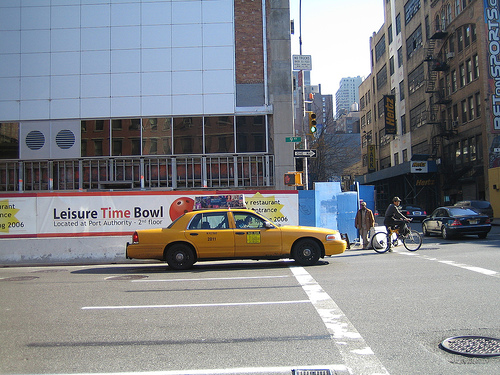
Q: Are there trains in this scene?
A: No, there are no trains.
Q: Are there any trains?
A: No, there are no trains.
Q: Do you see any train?
A: No, there are no trains.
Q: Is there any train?
A: No, there are no trains.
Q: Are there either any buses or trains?
A: No, there are no trains or buses.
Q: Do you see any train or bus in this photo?
A: No, there are no trains or buses.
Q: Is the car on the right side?
A: Yes, the car is on the right of the image.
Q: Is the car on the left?
A: No, the car is on the right of the image.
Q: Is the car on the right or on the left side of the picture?
A: The car is on the right of the image.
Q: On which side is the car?
A: The car is on the right of the image.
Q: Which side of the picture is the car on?
A: The car is on the right of the image.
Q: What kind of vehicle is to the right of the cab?
A: The vehicle is a car.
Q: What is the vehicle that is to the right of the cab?
A: The vehicle is a car.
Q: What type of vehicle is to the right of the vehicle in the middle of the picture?
A: The vehicle is a car.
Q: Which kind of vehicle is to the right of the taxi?
A: The vehicle is a car.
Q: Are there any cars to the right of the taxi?
A: Yes, there is a car to the right of the taxi.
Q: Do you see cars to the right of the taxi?
A: Yes, there is a car to the right of the taxi.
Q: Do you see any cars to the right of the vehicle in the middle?
A: Yes, there is a car to the right of the taxi.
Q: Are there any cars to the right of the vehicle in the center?
A: Yes, there is a car to the right of the taxi.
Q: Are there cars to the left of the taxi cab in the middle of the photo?
A: No, the car is to the right of the cab.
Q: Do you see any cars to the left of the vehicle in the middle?
A: No, the car is to the right of the cab.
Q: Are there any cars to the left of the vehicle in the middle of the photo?
A: No, the car is to the right of the cab.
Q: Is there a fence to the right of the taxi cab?
A: No, there is a car to the right of the taxi cab.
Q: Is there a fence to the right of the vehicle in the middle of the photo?
A: No, there is a car to the right of the taxi cab.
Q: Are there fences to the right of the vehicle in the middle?
A: No, there is a car to the right of the taxi cab.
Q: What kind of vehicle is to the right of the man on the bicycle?
A: The vehicle is a car.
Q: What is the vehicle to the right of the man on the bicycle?
A: The vehicle is a car.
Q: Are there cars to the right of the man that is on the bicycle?
A: Yes, there is a car to the right of the man.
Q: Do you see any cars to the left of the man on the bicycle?
A: No, the car is to the right of the man.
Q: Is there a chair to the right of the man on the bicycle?
A: No, there is a car to the right of the man.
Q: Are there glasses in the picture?
A: No, there are no glasses.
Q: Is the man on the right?
A: Yes, the man is on the right of the image.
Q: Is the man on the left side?
A: No, the man is on the right of the image.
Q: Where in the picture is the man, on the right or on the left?
A: The man is on the right of the image.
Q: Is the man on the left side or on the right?
A: The man is on the right of the image.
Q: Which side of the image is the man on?
A: The man is on the right of the image.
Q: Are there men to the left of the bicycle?
A: Yes, there is a man to the left of the bicycle.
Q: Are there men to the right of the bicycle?
A: No, the man is to the left of the bicycle.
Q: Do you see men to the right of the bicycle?
A: No, the man is to the left of the bicycle.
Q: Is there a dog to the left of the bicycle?
A: No, there is a man to the left of the bicycle.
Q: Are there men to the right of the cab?
A: Yes, there is a man to the right of the cab.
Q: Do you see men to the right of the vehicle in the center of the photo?
A: Yes, there is a man to the right of the cab.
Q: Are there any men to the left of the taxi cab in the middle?
A: No, the man is to the right of the cab.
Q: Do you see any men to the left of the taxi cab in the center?
A: No, the man is to the right of the cab.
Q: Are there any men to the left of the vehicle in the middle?
A: No, the man is to the right of the cab.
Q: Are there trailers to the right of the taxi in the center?
A: No, there is a man to the right of the taxi cab.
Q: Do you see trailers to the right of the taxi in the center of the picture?
A: No, there is a man to the right of the taxi cab.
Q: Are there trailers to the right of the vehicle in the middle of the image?
A: No, there is a man to the right of the taxi cab.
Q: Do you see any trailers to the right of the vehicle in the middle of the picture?
A: No, there is a man to the right of the taxi cab.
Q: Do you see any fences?
A: No, there are no fences.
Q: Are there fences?
A: No, there are no fences.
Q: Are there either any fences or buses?
A: No, there are no fences or buses.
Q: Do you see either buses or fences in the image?
A: No, there are no fences or buses.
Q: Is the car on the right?
A: Yes, the car is on the right of the image.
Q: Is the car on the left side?
A: No, the car is on the right of the image.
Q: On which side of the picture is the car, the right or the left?
A: The car is on the right of the image.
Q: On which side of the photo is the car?
A: The car is on the right of the image.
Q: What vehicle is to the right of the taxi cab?
A: The vehicle is a car.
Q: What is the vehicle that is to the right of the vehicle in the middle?
A: The vehicle is a car.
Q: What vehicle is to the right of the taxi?
A: The vehicle is a car.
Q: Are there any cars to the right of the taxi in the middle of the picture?
A: Yes, there is a car to the right of the cab.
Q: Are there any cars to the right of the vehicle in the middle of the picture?
A: Yes, there is a car to the right of the cab.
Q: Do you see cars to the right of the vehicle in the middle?
A: Yes, there is a car to the right of the cab.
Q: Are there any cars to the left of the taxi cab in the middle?
A: No, the car is to the right of the taxi.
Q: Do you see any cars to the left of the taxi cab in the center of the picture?
A: No, the car is to the right of the taxi.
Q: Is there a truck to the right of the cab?
A: No, there is a car to the right of the cab.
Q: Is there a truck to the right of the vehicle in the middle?
A: No, there is a car to the right of the cab.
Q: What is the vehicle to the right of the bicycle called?
A: The vehicle is a car.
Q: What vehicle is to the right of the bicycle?
A: The vehicle is a car.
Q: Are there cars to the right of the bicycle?
A: Yes, there is a car to the right of the bicycle.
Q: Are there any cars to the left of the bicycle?
A: No, the car is to the right of the bicycle.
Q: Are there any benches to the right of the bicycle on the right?
A: No, there is a car to the right of the bicycle.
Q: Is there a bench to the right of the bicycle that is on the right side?
A: No, there is a car to the right of the bicycle.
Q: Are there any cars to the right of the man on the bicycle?
A: Yes, there is a car to the right of the man.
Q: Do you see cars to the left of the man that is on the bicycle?
A: No, the car is to the right of the man.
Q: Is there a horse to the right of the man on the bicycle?
A: No, there is a car to the right of the man.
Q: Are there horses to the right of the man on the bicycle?
A: No, there is a car to the right of the man.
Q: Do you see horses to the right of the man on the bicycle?
A: No, there is a car to the right of the man.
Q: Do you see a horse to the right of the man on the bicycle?
A: No, there is a car to the right of the man.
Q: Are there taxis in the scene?
A: Yes, there is a taxi.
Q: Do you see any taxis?
A: Yes, there is a taxi.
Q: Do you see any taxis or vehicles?
A: Yes, there is a taxi.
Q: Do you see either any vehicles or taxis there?
A: Yes, there is a taxi.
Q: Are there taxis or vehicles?
A: Yes, there is a taxi.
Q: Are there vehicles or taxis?
A: Yes, there is a taxi.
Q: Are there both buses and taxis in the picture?
A: No, there is a taxi but no buses.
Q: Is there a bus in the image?
A: No, there are no buses.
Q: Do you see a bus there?
A: No, there are no buses.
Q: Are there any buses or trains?
A: No, there are no buses or trains.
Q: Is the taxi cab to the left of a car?
A: Yes, the taxi cab is to the left of a car.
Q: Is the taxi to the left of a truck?
A: No, the taxi is to the left of a car.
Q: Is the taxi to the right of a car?
A: No, the taxi is to the left of a car.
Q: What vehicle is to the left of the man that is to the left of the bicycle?
A: The vehicle is a taxi.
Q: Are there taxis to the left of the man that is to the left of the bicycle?
A: Yes, there is a taxi to the left of the man.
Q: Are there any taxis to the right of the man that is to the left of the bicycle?
A: No, the taxi is to the left of the man.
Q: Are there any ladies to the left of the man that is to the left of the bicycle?
A: No, there is a taxi to the left of the man.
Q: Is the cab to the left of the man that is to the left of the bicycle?
A: Yes, the cab is to the left of the man.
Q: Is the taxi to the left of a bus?
A: No, the taxi is to the left of the man.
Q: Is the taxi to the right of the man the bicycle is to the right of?
A: No, the taxi is to the left of the man.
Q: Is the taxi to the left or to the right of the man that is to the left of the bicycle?
A: The taxi is to the left of the man.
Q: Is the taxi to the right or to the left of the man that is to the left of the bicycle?
A: The taxi is to the left of the man.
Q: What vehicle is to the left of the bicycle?
A: The vehicle is a taxi.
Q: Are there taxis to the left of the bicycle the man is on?
A: Yes, there is a taxi to the left of the bicycle.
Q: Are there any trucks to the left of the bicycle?
A: No, there is a taxi to the left of the bicycle.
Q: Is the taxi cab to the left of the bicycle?
A: Yes, the taxi cab is to the left of the bicycle.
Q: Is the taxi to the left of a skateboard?
A: No, the taxi is to the left of the bicycle.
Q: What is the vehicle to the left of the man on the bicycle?
A: The vehicle is a taxi.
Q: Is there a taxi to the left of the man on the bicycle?
A: Yes, there is a taxi to the left of the man.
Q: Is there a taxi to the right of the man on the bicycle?
A: No, the taxi is to the left of the man.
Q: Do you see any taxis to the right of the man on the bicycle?
A: No, the taxi is to the left of the man.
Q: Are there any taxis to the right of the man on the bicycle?
A: No, the taxi is to the left of the man.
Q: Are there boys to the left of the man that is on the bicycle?
A: No, there is a taxi to the left of the man.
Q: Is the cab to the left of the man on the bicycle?
A: Yes, the cab is to the left of the man.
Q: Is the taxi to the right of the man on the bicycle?
A: No, the taxi is to the left of the man.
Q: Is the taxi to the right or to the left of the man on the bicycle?
A: The taxi is to the left of the man.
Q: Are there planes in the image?
A: No, there are no planes.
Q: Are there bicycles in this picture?
A: Yes, there is a bicycle.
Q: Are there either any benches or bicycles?
A: Yes, there is a bicycle.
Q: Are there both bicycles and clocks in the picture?
A: No, there is a bicycle but no clocks.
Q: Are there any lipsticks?
A: No, there are no lipsticks.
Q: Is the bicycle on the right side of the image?
A: Yes, the bicycle is on the right of the image.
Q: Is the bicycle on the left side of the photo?
A: No, the bicycle is on the right of the image.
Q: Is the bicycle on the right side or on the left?
A: The bicycle is on the right of the image.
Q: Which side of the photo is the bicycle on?
A: The bicycle is on the right of the image.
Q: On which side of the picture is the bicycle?
A: The bicycle is on the right of the image.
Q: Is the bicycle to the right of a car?
A: No, the bicycle is to the left of a car.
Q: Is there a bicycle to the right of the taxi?
A: Yes, there is a bicycle to the right of the taxi.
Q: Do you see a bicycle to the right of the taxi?
A: Yes, there is a bicycle to the right of the taxi.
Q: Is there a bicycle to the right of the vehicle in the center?
A: Yes, there is a bicycle to the right of the taxi.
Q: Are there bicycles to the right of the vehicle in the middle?
A: Yes, there is a bicycle to the right of the taxi.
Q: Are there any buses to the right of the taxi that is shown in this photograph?
A: No, there is a bicycle to the right of the taxi.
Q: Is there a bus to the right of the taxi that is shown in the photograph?
A: No, there is a bicycle to the right of the taxi.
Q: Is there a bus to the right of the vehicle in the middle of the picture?
A: No, there is a bicycle to the right of the taxi.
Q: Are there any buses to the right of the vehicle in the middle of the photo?
A: No, there is a bicycle to the right of the taxi.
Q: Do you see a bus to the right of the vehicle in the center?
A: No, there is a bicycle to the right of the taxi.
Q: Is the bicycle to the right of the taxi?
A: Yes, the bicycle is to the right of the taxi.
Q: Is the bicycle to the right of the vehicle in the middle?
A: Yes, the bicycle is to the right of the taxi.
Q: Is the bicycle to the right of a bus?
A: No, the bicycle is to the right of the taxi.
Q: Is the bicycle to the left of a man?
A: No, the bicycle is to the right of a man.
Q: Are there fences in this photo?
A: No, there are no fences.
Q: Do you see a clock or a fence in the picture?
A: No, there are no fences or clocks.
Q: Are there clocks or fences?
A: No, there are no fences or clocks.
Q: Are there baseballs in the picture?
A: No, there are no baseballs.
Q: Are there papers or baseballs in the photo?
A: No, there are no baseballs or papers.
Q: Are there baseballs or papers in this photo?
A: No, there are no baseballs or papers.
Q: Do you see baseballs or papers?
A: No, there are no baseballs or papers.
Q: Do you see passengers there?
A: No, there are no passengers.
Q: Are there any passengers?
A: No, there are no passengers.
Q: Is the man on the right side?
A: Yes, the man is on the right of the image.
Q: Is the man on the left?
A: No, the man is on the right of the image.